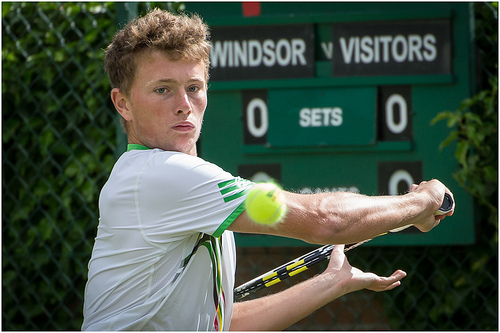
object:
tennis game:
[72, 6, 468, 331]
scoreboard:
[170, 0, 478, 249]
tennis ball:
[240, 185, 291, 228]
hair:
[99, 10, 218, 91]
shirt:
[74, 143, 273, 332]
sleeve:
[153, 158, 258, 243]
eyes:
[152, 85, 172, 96]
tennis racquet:
[233, 192, 457, 301]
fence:
[0, 0, 127, 333]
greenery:
[450, 96, 499, 160]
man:
[80, 8, 450, 333]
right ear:
[108, 87, 132, 122]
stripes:
[195, 237, 240, 284]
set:
[296, 107, 345, 129]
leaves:
[464, 164, 500, 192]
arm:
[204, 167, 403, 248]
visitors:
[338, 33, 438, 65]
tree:
[439, 94, 499, 214]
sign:
[195, 21, 445, 79]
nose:
[172, 91, 193, 116]